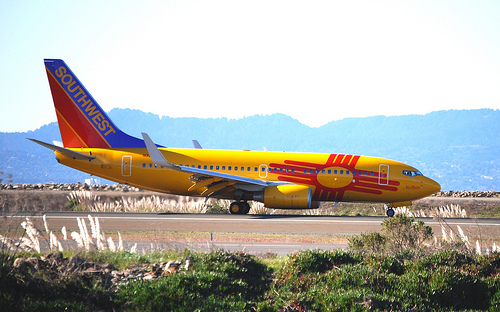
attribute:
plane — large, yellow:
[24, 58, 442, 218]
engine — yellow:
[249, 183, 313, 210]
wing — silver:
[141, 130, 299, 199]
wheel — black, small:
[228, 201, 243, 215]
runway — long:
[1, 209, 499, 226]